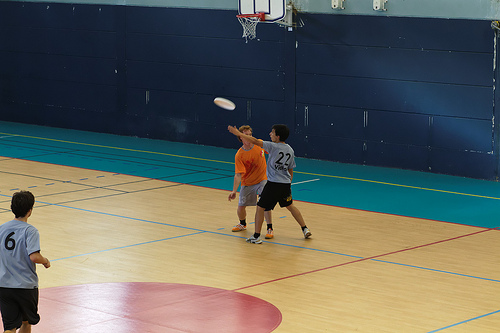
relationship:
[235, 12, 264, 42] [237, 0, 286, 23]
basketball on backboard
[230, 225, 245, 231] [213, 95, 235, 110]
orange sneaker on frisbee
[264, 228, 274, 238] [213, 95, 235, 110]
orange sneaker on frisbee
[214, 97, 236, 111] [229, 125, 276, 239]
frisbee on boy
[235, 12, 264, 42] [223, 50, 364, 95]
basketball attached to wall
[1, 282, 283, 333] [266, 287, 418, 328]
circle on floor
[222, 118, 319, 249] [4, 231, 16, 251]
boy wearing a 6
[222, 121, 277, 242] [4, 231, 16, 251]
boy wearing a 6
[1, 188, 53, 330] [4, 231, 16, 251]
boy wearing a 6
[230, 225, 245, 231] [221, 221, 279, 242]
orange sneaker on feet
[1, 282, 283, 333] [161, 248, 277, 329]
circle on ground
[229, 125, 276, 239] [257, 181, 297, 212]
boy wearing black shorts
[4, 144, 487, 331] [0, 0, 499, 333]
floor in court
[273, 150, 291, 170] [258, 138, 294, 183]
number 22 on back shirt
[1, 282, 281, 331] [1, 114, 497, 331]
circle on court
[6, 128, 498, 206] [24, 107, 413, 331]
yellow line on court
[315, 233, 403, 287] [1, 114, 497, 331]
line on court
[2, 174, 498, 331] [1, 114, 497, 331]
blue lines on court